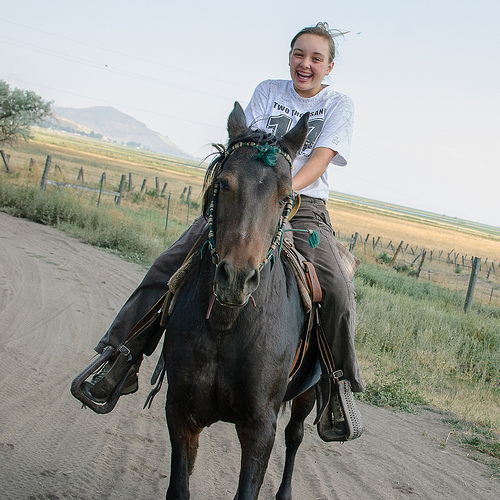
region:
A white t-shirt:
[222, 84, 350, 199]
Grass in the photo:
[365, 295, 475, 395]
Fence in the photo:
[421, 252, 498, 299]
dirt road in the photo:
[12, 317, 59, 420]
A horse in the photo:
[167, 144, 307, 436]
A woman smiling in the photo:
[209, 19, 351, 186]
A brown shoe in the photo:
[75, 341, 150, 398]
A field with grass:
[388, 209, 443, 244]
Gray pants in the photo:
[310, 229, 355, 329]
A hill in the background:
[79, 96, 154, 149]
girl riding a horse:
[71, 20, 411, 498]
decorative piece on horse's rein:
[223, 139, 293, 169]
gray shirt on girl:
[243, 77, 355, 200]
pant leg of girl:
[300, 193, 359, 396]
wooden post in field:
[465, 258, 484, 314]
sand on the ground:
[5, 219, 70, 494]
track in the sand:
[16, 459, 46, 472]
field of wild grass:
[378, 289, 451, 361]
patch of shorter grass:
[371, 376, 425, 411]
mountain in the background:
[63, 102, 183, 159]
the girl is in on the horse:
[79, 35, 389, 457]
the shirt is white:
[242, 77, 354, 192]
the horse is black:
[155, 171, 385, 498]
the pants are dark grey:
[302, 213, 373, 382]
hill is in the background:
[71, 94, 173, 162]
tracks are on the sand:
[40, 246, 128, 291]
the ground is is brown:
[9, 249, 120, 299]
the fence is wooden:
[372, 234, 496, 300]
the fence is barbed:
[361, 228, 451, 270]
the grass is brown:
[401, 356, 479, 430]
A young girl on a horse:
[83, 23, 362, 430]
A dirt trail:
[2, 212, 477, 498]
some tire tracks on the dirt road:
[7, 278, 137, 498]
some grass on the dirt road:
[13, 242, 64, 270]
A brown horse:
[159, 102, 319, 499]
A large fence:
[0, 151, 497, 318]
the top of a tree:
[0, 80, 56, 146]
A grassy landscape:
[2, 121, 498, 461]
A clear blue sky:
[0, 2, 499, 224]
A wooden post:
[463, 258, 478, 314]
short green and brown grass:
[78, 200, 116, 214]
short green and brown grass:
[129, 187, 151, 223]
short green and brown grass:
[352, 318, 400, 360]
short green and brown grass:
[395, 330, 462, 376]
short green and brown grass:
[370, 316, 435, 360]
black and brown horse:
[191, 132, 303, 417]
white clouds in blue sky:
[56, 22, 158, 77]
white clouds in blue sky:
[134, 22, 209, 62]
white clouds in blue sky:
[354, 30, 396, 70]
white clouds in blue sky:
[378, 114, 494, 183]